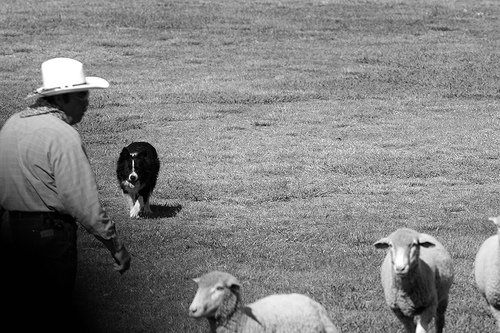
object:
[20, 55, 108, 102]
cowboy hat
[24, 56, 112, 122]
head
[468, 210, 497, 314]
sheep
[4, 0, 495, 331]
field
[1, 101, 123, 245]
shirt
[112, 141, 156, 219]
sheepdog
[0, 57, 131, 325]
man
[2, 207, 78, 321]
black pants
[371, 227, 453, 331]
sheep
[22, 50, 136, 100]
hat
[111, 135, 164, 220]
dog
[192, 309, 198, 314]
nose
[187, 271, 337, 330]
sheep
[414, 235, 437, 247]
ears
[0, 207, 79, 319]
pants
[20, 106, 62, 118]
bandanna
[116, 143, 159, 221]
black dog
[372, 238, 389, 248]
ear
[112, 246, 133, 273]
glove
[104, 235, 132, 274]
hand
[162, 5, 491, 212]
grass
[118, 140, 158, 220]
animal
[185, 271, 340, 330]
animal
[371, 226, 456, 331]
animal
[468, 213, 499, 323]
animal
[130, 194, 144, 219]
leg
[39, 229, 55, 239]
tag